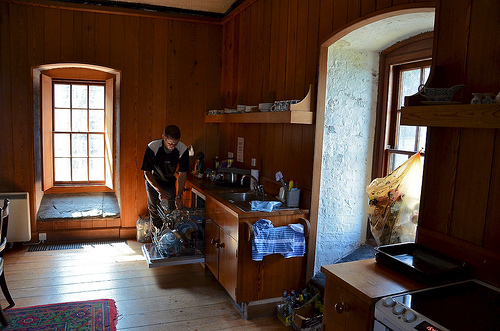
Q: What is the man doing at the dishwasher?
A: Placing dishes in dishwasher.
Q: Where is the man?
A: Kitchen.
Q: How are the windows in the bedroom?
A: Arched with no shades.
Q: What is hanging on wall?
A: A bag.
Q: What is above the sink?
A: Dishes.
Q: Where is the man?
A: In the kitchen.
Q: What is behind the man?
A: Window.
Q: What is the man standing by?
A: A window.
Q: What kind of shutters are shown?
A: Wooden.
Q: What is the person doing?
A: Filling a dishwasher.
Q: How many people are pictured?
A: One.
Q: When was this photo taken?
A: During the daytime.